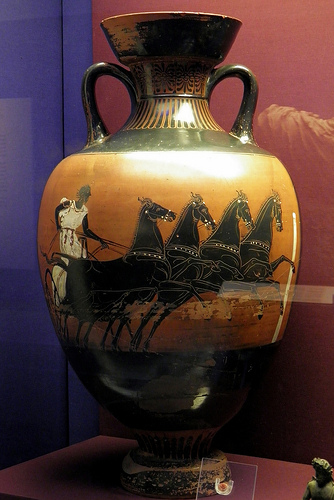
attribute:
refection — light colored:
[187, 379, 214, 414]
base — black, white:
[120, 448, 234, 496]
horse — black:
[241, 189, 294, 318]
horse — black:
[125, 189, 271, 350]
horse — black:
[107, 190, 242, 350]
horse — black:
[39, 193, 208, 342]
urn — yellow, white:
[75, 28, 296, 426]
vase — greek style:
[26, 6, 310, 496]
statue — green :
[302, 455, 333, 497]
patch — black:
[97, 346, 243, 406]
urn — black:
[34, 10, 318, 497]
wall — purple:
[0, 362, 62, 440]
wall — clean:
[275, 31, 314, 95]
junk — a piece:
[210, 469, 235, 495]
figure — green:
[303, 455, 332, 498]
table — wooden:
[0, 464, 109, 497]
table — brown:
[33, 412, 168, 498]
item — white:
[214, 477, 234, 495]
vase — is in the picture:
[14, 28, 320, 439]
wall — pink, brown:
[85, 0, 334, 465]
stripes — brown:
[101, 236, 179, 282]